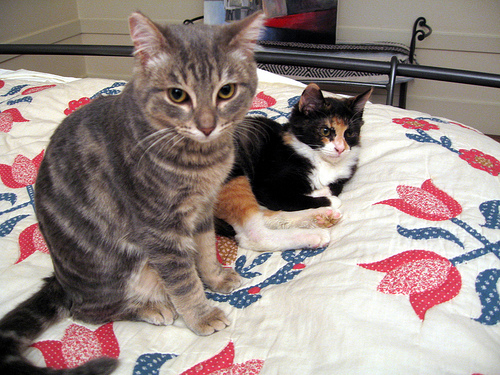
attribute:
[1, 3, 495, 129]
wall — white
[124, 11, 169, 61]
ear — small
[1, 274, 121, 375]
tail — long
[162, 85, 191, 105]
eye — yellow, small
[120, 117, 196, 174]
whiskers — white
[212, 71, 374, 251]
cat — black, dark, brown, white, laying, orange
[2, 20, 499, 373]
blanket — light, white, large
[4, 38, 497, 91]
pole — metal, skinny, black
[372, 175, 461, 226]
flower — red, light, bright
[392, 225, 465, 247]
stem — blue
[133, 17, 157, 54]
hair — white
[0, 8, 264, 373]
cat — inside, still, light, sitting, grey, staring, small